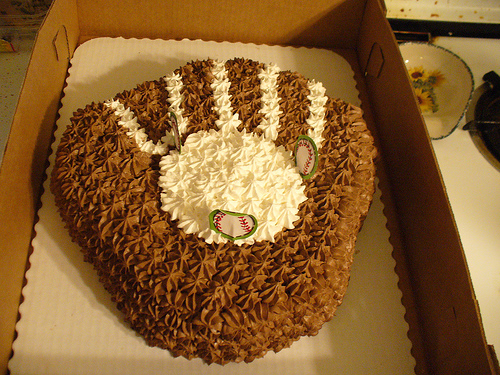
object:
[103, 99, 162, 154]
icing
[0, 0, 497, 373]
delivery box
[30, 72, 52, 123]
part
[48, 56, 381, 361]
frosting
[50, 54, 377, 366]
cake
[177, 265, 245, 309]
icing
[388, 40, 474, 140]
saucer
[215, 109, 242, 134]
star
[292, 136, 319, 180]
baseball decoration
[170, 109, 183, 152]
decoration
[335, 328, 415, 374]
paper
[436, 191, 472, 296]
border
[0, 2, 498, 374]
box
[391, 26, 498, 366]
counter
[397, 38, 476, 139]
tan bowl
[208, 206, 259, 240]
baseball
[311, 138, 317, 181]
border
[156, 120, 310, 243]
circle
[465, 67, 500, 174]
stove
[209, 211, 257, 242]
decoration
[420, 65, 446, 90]
daisy